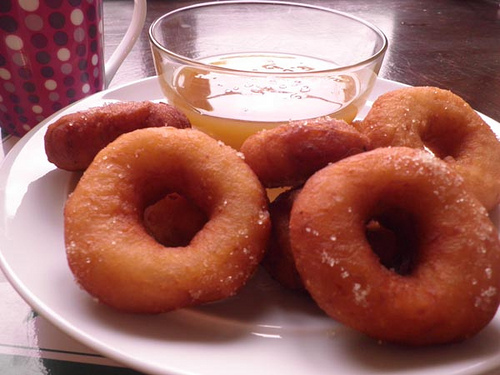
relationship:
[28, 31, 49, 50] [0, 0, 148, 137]
polka dot on side of coffee cup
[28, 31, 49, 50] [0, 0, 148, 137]
polka dot printed on coffee cup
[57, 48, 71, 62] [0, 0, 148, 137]
polka dot showing on coffee cup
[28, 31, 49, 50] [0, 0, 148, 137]
polka dot inked on coffee cup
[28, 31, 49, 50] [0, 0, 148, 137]
polka dot shown on coffee cup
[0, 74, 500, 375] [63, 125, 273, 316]
plate has donut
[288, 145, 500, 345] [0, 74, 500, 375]
donut sitting on plate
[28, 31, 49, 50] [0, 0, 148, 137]
polka dot on surface of coffee cup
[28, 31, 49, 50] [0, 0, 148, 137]
polka dot visible on coffee cup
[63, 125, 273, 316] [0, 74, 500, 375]
donut sitting on plate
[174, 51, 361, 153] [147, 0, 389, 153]
sauce sitting in bowl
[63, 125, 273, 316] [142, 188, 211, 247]
donut has hole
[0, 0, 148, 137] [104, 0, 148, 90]
coffee cup has handle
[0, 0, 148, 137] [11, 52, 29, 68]
coffee cup has polka dot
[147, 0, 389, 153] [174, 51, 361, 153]
bowl has sauce